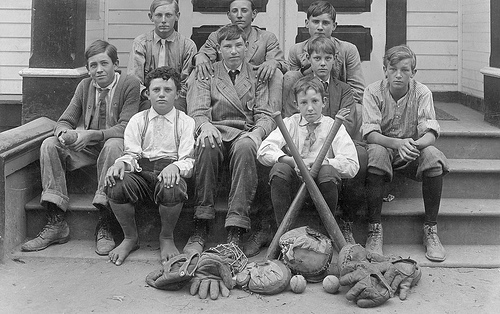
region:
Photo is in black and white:
[5, 3, 492, 309]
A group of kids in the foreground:
[10, 2, 462, 270]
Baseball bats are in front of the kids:
[257, 97, 362, 259]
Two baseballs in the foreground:
[283, 268, 345, 301]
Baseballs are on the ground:
[280, 258, 347, 305]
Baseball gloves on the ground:
[146, 224, 435, 308]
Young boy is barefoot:
[94, 63, 200, 281]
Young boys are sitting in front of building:
[7, 3, 472, 261]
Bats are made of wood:
[256, 103, 369, 264]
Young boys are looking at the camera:
[18, 0, 462, 269]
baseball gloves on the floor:
[149, 223, 441, 311]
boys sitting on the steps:
[36, 14, 464, 303]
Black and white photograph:
[3, 3, 497, 308]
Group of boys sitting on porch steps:
[35, 4, 421, 248]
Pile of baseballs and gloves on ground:
[155, 229, 420, 295]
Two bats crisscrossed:
[268, 109, 349, 259]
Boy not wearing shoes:
[107, 68, 195, 271]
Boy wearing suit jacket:
[185, 28, 280, 139]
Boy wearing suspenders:
[127, 68, 187, 160]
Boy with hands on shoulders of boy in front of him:
[195, 3, 279, 84]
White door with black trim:
[355, 0, 411, 50]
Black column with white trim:
[20, 5, 87, 109]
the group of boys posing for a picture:
[20, 0, 448, 265]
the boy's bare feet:
[107, 236, 179, 264]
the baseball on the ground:
[290, 274, 306, 294]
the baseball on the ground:
[323, 274, 340, 293]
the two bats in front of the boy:
[266, 107, 345, 257]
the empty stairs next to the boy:
[440, 128, 498, 244]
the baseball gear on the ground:
[144, 226, 422, 307]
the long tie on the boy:
[97, 89, 107, 129]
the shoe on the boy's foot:
[420, 222, 445, 260]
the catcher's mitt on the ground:
[189, 257, 234, 299]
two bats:
[264, 102, 356, 261]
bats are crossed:
[264, 105, 363, 278]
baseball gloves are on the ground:
[148, 222, 429, 312]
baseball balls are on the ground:
[277, 272, 340, 286]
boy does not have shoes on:
[115, 226, 181, 272]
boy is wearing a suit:
[206, 62, 286, 143]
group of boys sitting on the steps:
[16, 6, 474, 264]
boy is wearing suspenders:
[134, 105, 199, 168]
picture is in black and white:
[30, 38, 494, 277]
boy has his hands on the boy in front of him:
[190, 1, 292, 87]